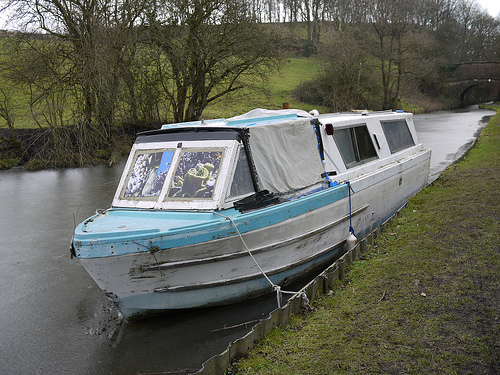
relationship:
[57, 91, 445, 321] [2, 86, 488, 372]
boat in water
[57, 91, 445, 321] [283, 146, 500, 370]
boat tied to shore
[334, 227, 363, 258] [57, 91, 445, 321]
bumper on side boat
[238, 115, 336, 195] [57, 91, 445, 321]
canvas over side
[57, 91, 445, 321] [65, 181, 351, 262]
boat area blue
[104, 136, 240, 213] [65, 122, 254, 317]
window on front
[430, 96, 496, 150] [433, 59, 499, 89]
body of water under bridge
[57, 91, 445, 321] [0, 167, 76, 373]
boat docked on river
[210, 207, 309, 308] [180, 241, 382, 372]
rope tied to fence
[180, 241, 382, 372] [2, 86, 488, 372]
fence along river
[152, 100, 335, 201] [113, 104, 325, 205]
fabric over cabin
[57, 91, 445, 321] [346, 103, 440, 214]
boat has color white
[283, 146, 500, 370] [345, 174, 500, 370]
area has grass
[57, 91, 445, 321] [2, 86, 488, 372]
boat on water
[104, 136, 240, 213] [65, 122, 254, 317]
screen in front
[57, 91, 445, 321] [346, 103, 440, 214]
boat color white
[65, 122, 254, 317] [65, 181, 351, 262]
front color blue